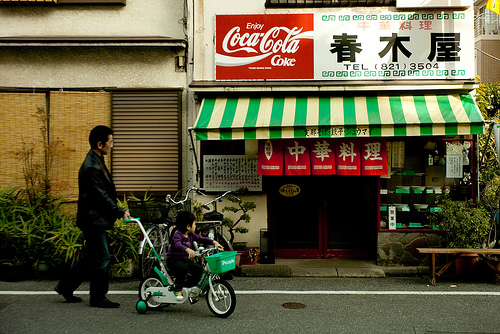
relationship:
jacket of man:
[69, 147, 124, 239] [52, 121, 121, 307]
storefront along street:
[182, 1, 487, 285] [0, 277, 497, 331]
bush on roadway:
[424, 199, 492, 249] [1, 269, 495, 333]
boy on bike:
[154, 204, 214, 286] [135, 189, 283, 324]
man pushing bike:
[54, 123, 134, 308] [122, 209, 237, 316]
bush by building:
[10, 194, 75, 244] [7, 51, 192, 221]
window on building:
[114, 92, 183, 187] [9, 8, 498, 250]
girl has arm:
[167, 204, 227, 258] [173, 235, 200, 256]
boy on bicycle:
[164, 210, 226, 293] [122, 218, 239, 315]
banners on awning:
[254, 138, 392, 178] [190, 94, 491, 143]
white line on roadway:
[2, 285, 499, 302] [0, 275, 499, 333]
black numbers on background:
[375, 61, 391, 78] [199, 5, 477, 77]